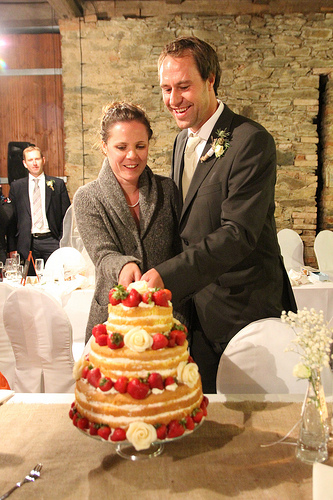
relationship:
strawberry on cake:
[117, 289, 140, 307] [69, 280, 209, 450]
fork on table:
[3, 463, 43, 499] [0, 390, 331, 498]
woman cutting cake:
[73, 96, 193, 358] [69, 280, 209, 450]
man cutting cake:
[139, 35, 297, 393] [69, 280, 209, 450]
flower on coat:
[200, 128, 231, 162] [153, 104, 297, 353]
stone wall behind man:
[59, 11, 332, 269] [139, 35, 297, 393]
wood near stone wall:
[0, 34, 68, 200] [59, 11, 332, 269]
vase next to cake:
[295, 372, 326, 464] [69, 280, 209, 450]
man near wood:
[8, 146, 72, 275] [0, 34, 68, 200]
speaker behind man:
[7, 140, 34, 185] [8, 146, 72, 275]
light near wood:
[1, 38, 9, 72] [0, 34, 68, 200]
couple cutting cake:
[73, 27, 299, 392] [69, 280, 209, 450]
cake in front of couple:
[69, 280, 209, 450] [73, 27, 299, 392]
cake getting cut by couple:
[69, 280, 209, 450] [73, 27, 299, 392]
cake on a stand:
[69, 280, 209, 450] [75, 416, 206, 461]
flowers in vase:
[279, 308, 332, 415] [295, 372, 326, 464]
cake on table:
[69, 280, 209, 450] [0, 390, 331, 498]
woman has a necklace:
[73, 96, 193, 358] [125, 199, 139, 209]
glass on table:
[32, 258, 45, 281] [1, 276, 96, 342]